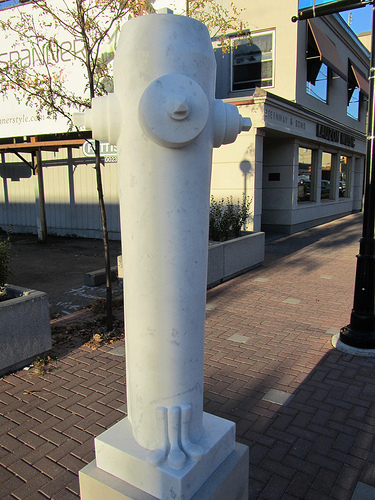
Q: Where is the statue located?
A: Sidewalk.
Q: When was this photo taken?
A: Daytime.